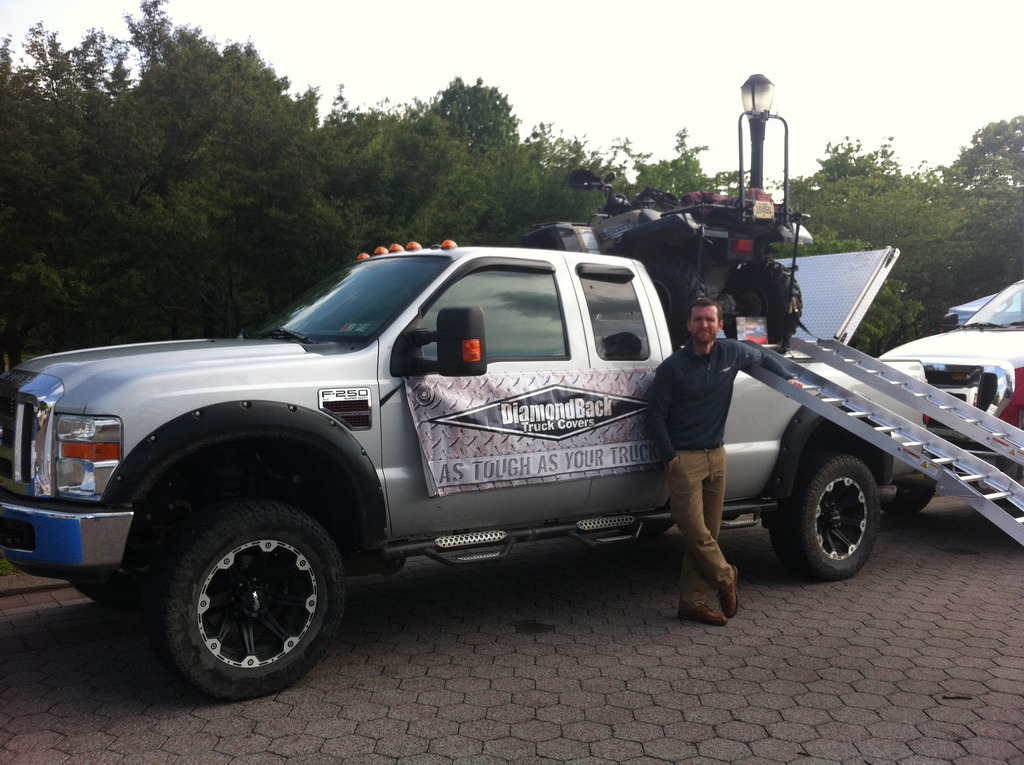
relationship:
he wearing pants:
[645, 309, 751, 621] [668, 439, 746, 627]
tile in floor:
[318, 703, 381, 736] [301, 651, 881, 758]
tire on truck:
[151, 484, 353, 701] [0, 242, 907, 705]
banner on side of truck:
[402, 366, 667, 499] [10, 225, 911, 707]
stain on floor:
[500, 605, 561, 640] [0, 492, 1024, 764]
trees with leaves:
[766, 121, 1022, 359] [874, 139, 900, 179]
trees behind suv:
[766, 121, 1022, 359] [863, 262, 1023, 511]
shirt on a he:
[645, 338, 784, 457] [647, 297, 803, 627]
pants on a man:
[663, 444, 741, 615] [643, 292, 790, 621]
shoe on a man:
[677, 600, 727, 625] [643, 292, 790, 621]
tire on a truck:
[151, 484, 353, 701] [10, 225, 911, 707]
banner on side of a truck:
[393, 364, 675, 505] [0, 186, 910, 684]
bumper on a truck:
[0, 487, 143, 580] [10, 225, 911, 707]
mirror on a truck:
[386, 301, 490, 381] [10, 225, 911, 707]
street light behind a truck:
[736, 61, 791, 202] [10, 225, 911, 707]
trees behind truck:
[6, 1, 966, 289] [10, 225, 911, 707]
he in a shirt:
[647, 297, 803, 627] [645, 338, 784, 457]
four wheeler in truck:
[521, 158, 817, 353] [10, 225, 911, 707]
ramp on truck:
[737, 337, 1024, 550] [10, 225, 911, 707]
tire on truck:
[151, 484, 353, 701] [10, 225, 911, 707]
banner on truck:
[402, 366, 667, 499] [10, 225, 911, 707]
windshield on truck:
[283, 253, 444, 346] [10, 225, 911, 707]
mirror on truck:
[389, 306, 487, 378] [10, 225, 911, 707]